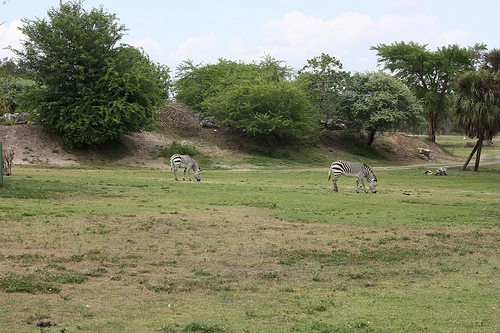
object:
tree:
[370, 36, 486, 143]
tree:
[448, 53, 499, 172]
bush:
[2, 0, 172, 156]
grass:
[331, 267, 376, 328]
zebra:
[327, 159, 378, 193]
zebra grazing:
[169, 153, 202, 181]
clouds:
[264, 15, 463, 53]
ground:
[1, 118, 498, 329]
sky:
[0, 0, 500, 96]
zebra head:
[368, 180, 378, 193]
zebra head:
[193, 171, 202, 181]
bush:
[200, 75, 324, 146]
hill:
[2, 112, 444, 173]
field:
[2, 130, 497, 330]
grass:
[199, 180, 413, 227]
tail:
[327, 166, 332, 181]